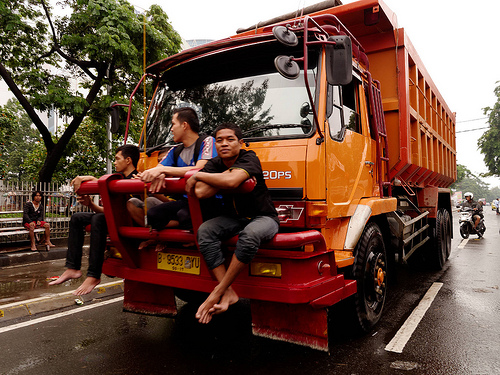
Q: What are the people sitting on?
A: A truck.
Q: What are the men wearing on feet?
A: None.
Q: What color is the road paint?
A: White.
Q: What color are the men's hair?
A: Black.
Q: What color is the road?
A: Gray.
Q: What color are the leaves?
A: Green.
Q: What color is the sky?
A: White.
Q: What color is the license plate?
A: Yellow.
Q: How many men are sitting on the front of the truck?
A: 3.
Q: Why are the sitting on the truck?
A: Taking a photograph.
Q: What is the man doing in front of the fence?
A: Sitting on a bench.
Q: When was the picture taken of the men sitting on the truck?
A: Rainy afternoon.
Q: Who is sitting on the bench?
A: Another man.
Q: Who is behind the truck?
A: Man on a motorcycle.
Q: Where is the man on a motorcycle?
A: On the street behind the truck.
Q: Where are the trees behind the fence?
A: City park.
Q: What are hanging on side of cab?
A: Side view mirrors.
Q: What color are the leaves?
A: Green.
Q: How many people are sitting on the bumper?
A: Three.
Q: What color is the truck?
A: Orange.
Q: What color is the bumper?
A: Red.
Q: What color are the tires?
A: Black.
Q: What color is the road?
A: Black.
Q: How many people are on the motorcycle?
A: One.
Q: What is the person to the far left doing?
A: Sitting.